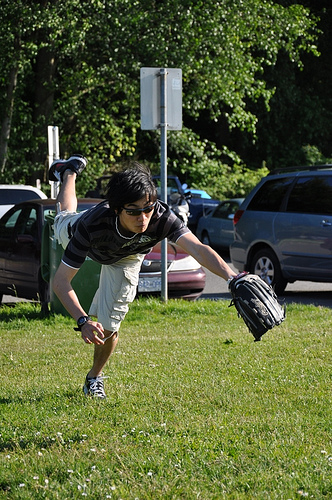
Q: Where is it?
A: This is at the parking lot.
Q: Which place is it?
A: It is a parking lot.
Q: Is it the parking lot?
A: Yes, it is the parking lot.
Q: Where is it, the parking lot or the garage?
A: It is the parking lot.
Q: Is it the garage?
A: No, it is the parking lot.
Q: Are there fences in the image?
A: No, there are no fences.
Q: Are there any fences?
A: No, there are no fences.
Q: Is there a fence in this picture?
A: No, there are no fences.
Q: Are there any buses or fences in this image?
A: No, there are no fences or buses.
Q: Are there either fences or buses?
A: No, there are no fences or buses.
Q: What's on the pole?
A: The sign is on the pole.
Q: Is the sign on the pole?
A: Yes, the sign is on the pole.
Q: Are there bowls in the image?
A: No, there are no bowls.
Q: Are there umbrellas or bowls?
A: No, there are no bowls or umbrellas.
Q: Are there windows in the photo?
A: Yes, there is a window.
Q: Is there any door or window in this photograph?
A: Yes, there is a window.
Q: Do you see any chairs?
A: No, there are no chairs.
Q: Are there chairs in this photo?
A: No, there are no chairs.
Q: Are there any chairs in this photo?
A: No, there are no chairs.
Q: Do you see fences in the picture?
A: No, there are no fences.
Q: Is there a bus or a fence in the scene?
A: No, there are no fences or buses.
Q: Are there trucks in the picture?
A: No, there are no trucks.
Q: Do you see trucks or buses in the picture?
A: No, there are no trucks or buses.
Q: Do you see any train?
A: No, there are no trains.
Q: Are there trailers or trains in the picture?
A: No, there are no trains or trailers.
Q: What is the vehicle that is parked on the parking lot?
A: The vehicle is a car.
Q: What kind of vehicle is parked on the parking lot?
A: The vehicle is a car.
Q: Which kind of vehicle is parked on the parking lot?
A: The vehicle is a car.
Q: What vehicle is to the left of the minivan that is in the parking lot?
A: The vehicle is a car.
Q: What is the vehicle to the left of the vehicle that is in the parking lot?
A: The vehicle is a car.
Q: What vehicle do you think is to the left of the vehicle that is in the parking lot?
A: The vehicle is a car.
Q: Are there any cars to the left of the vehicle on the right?
A: Yes, there is a car to the left of the minivan.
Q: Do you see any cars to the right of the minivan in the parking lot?
A: No, the car is to the left of the minivan.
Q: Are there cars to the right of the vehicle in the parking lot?
A: No, the car is to the left of the minivan.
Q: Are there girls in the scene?
A: No, there are no girls.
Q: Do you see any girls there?
A: No, there are no girls.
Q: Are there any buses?
A: No, there are no buses.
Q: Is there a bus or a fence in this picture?
A: No, there are no buses or fences.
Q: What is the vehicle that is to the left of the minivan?
A: The vehicle is a car.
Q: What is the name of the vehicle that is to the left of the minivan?
A: The vehicle is a car.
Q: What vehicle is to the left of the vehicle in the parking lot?
A: The vehicle is a car.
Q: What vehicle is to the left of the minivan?
A: The vehicle is a car.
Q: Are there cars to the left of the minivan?
A: Yes, there is a car to the left of the minivan.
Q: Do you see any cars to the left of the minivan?
A: Yes, there is a car to the left of the minivan.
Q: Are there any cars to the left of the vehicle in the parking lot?
A: Yes, there is a car to the left of the minivan.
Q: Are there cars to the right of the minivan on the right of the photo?
A: No, the car is to the left of the minivan.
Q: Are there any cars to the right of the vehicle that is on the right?
A: No, the car is to the left of the minivan.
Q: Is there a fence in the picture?
A: No, there are no fences.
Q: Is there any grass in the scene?
A: Yes, there is grass.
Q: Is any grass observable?
A: Yes, there is grass.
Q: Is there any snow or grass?
A: Yes, there is grass.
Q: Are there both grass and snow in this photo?
A: No, there is grass but no snow.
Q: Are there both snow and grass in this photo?
A: No, there is grass but no snow.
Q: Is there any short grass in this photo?
A: Yes, there is short grass.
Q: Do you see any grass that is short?
A: Yes, there is grass that is short.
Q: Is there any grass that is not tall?
A: Yes, there is short grass.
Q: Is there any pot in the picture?
A: No, there are no pots.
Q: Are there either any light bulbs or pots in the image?
A: No, there are no pots or light bulbs.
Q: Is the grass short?
A: Yes, the grass is short.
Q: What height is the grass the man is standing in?
A: The grass is short.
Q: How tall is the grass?
A: The grass is short.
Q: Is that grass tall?
A: No, the grass is short.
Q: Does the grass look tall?
A: No, the grass is short.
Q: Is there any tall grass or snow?
A: No, there is grass but it is short.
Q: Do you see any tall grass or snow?
A: No, there is grass but it is short.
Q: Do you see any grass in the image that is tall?
A: No, there is grass but it is short.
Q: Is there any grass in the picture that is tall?
A: No, there is grass but it is short.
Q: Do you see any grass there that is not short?
A: No, there is grass but it is short.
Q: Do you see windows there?
A: Yes, there is a window.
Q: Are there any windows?
A: Yes, there is a window.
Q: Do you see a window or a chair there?
A: Yes, there is a window.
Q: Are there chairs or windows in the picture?
A: Yes, there is a window.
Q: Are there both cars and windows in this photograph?
A: Yes, there are both a window and a car.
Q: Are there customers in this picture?
A: No, there are no customers.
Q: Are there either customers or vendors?
A: No, there are no customers or vendors.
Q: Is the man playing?
A: Yes, the man is playing.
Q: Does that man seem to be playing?
A: Yes, the man is playing.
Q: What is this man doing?
A: The man is playing.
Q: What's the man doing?
A: The man is playing.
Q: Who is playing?
A: The man is playing.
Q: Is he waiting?
A: No, the man is playing.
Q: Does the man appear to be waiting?
A: No, the man is playing.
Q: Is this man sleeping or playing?
A: The man is playing.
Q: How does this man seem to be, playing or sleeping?
A: The man is playing.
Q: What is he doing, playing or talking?
A: The man is playing.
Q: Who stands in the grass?
A: The man stands in the grass.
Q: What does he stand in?
A: The man stands in the grass.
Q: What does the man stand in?
A: The man stands in the grass.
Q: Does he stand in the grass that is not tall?
A: Yes, the man stands in the grass.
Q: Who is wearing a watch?
A: The man is wearing a watch.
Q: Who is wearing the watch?
A: The man is wearing a watch.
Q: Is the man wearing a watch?
A: Yes, the man is wearing a watch.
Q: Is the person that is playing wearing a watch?
A: Yes, the man is wearing a watch.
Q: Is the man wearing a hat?
A: No, the man is wearing a watch.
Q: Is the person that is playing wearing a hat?
A: No, the man is wearing a watch.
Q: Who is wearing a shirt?
A: The man is wearing a shirt.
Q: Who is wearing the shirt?
A: The man is wearing a shirt.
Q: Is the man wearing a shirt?
A: Yes, the man is wearing a shirt.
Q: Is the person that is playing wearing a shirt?
A: Yes, the man is wearing a shirt.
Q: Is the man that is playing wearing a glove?
A: No, the man is wearing a shirt.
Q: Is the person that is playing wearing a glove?
A: No, the man is wearing a shirt.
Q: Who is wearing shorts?
A: The man is wearing shorts.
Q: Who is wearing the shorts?
A: The man is wearing shorts.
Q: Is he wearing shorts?
A: Yes, the man is wearing shorts.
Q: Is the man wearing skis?
A: No, the man is wearing shorts.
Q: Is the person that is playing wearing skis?
A: No, the man is wearing shorts.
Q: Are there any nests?
A: No, there are no nests.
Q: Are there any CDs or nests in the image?
A: No, there are no nests or cds.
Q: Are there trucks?
A: No, there are no trucks.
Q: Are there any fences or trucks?
A: No, there are no trucks or fences.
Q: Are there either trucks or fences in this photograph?
A: No, there are no trucks or fences.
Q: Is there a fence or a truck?
A: No, there are no trucks or fences.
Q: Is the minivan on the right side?
A: Yes, the minivan is on the right of the image.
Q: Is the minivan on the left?
A: No, the minivan is on the right of the image.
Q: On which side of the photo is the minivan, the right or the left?
A: The minivan is on the right of the image.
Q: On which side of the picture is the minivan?
A: The minivan is on the right of the image.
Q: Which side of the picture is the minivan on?
A: The minivan is on the right of the image.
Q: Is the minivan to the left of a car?
A: No, the minivan is to the right of a car.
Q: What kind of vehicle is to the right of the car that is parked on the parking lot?
A: The vehicle is a minivan.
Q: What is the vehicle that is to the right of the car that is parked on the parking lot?
A: The vehicle is a minivan.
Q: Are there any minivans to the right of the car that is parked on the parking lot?
A: Yes, there is a minivan to the right of the car.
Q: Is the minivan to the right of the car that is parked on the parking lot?
A: Yes, the minivan is to the right of the car.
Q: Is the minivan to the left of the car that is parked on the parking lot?
A: No, the minivan is to the right of the car.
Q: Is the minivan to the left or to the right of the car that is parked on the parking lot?
A: The minivan is to the right of the car.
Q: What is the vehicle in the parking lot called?
A: The vehicle is a minivan.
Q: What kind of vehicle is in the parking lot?
A: The vehicle is a minivan.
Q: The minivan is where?
A: The minivan is in the parking lot.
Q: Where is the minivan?
A: The minivan is in the parking lot.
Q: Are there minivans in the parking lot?
A: Yes, there is a minivan in the parking lot.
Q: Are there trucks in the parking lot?
A: No, there is a minivan in the parking lot.